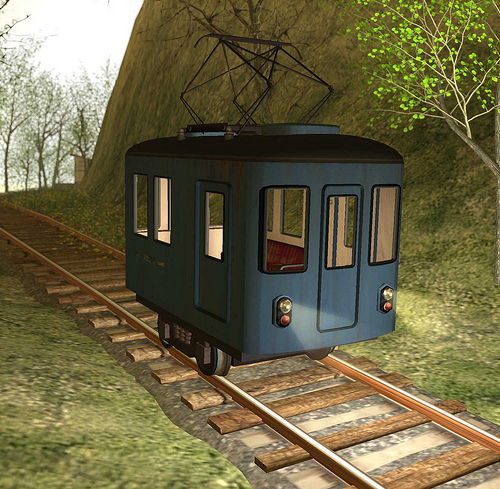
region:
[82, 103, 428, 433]
a blue cartoon train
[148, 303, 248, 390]
the wheels of the cartoon train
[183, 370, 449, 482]
the train tracks under the train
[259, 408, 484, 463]
wooden slats of train tracks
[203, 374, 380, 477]
metal rails of train tracks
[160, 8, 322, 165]
bars coming out of the top of the train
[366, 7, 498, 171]
the brown branch of a tree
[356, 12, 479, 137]
green leaves on a tree branch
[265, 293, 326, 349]
red and white lights on the train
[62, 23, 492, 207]
rocky wall behind the train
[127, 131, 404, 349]
A train car on the track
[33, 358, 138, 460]
The grass is next to the track.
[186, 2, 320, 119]
Wires on top of the car.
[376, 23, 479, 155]
A tree on the hill.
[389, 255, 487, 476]
The tracks next to the hill.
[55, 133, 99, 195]
A building in the background.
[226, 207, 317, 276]
A seat on the train car.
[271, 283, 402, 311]
Headlights on the train car.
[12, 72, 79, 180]
Trees in the background.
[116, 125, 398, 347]
The train car is gray.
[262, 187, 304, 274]
A train window in the photo.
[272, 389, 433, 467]
railway line in the photo.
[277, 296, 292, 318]
Headlights in the photo.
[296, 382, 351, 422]
Wooden bar in the photo.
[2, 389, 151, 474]
Green grass in the picture.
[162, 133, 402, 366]
Train coach in the photo.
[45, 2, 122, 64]
Cloudy skies in the photo.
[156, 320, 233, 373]
Train wheels in the photo.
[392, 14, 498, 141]
Tree in the photo.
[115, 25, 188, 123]
A hill in the photo.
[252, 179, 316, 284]
This is a window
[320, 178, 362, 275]
This is a window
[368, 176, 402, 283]
This is a window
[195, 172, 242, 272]
This is a window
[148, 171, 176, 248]
This is a window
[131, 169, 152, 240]
This is a window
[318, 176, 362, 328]
This is a door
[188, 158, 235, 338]
This is a door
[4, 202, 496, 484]
This is a railway line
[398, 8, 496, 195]
This is a tree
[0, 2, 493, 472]
scene is an animation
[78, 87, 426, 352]
train on the tracks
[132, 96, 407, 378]
only 1 train cart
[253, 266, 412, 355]
lights on train turned on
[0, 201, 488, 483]
train tracks are brown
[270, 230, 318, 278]
train seats are red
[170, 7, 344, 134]
black structure above cart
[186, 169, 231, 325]
train door is closed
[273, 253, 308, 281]
metal railing next to seat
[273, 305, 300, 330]
the light is orange